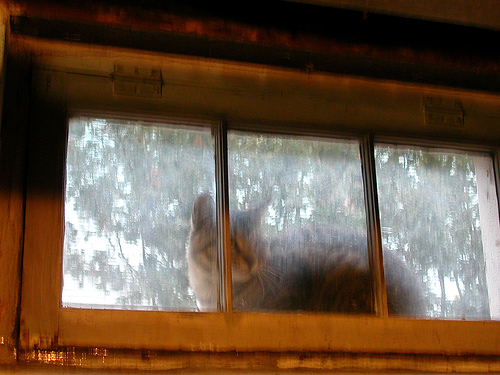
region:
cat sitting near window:
[184, 167, 406, 320]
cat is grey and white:
[168, 192, 365, 323]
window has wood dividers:
[196, 123, 398, 324]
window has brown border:
[116, 301, 447, 364]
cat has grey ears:
[182, 183, 335, 253]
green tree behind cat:
[93, 116, 244, 280]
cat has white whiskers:
[234, 256, 290, 305]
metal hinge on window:
[99, 51, 169, 111]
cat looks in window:
[173, 170, 408, 325]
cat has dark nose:
[233, 247, 262, 274]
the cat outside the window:
[189, 190, 421, 315]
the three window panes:
[38, 101, 498, 348]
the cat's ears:
[191, 190, 279, 215]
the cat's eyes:
[218, 232, 264, 254]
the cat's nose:
[243, 251, 255, 266]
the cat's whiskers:
[256, 264, 284, 297]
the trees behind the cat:
[73, 122, 484, 310]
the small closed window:
[9, 98, 498, 363]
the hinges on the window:
[109, 60, 469, 126]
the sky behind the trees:
[72, 134, 159, 306]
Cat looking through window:
[187, 187, 439, 314]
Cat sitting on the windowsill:
[186, 187, 425, 319]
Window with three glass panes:
[60, 98, 499, 330]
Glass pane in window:
[221, 113, 376, 331]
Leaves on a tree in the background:
[98, 142, 180, 297]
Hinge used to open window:
[100, 55, 180, 97]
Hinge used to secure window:
[415, 89, 475, 136]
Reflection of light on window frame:
[10, 340, 93, 372]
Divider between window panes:
[202, 108, 240, 324]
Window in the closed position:
[16, 59, 486, 364]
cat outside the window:
[163, 191, 439, 321]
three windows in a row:
[61, 118, 495, 338]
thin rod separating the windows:
[201, 121, 242, 313]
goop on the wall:
[26, 345, 103, 366]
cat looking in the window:
[168, 187, 438, 320]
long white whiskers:
[248, 260, 289, 298]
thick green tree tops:
[71, 125, 493, 323]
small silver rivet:
[417, 86, 474, 126]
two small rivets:
[94, 56, 497, 142]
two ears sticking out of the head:
[182, 181, 284, 228]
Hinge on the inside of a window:
[109, 62, 166, 98]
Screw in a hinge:
[424, 112, 436, 122]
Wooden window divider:
[209, 118, 240, 315]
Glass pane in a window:
[66, 111, 222, 312]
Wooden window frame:
[61, 305, 495, 355]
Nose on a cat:
[243, 257, 258, 272]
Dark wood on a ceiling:
[12, 5, 496, 78]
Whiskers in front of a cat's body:
[256, 264, 291, 297]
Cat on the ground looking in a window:
[181, 194, 427, 320]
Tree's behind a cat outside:
[83, 135, 200, 296]